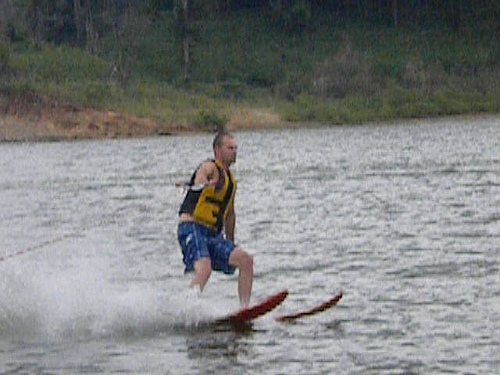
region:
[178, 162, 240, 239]
black and yellow life vest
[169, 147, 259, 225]
black and yellow life vest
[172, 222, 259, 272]
the shorts is blue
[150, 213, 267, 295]
the shorts is blue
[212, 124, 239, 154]
man has short hair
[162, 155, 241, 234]
yellow and black vest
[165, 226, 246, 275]
man has blue shorts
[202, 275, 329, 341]
red skis on water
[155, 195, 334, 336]
man is on skis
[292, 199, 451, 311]
water is light grey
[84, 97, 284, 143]
brown dirt on shore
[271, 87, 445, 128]
green plants on shore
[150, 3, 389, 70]
green trees in distance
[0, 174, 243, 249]
cable next to man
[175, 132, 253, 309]
the man on the water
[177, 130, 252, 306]
the man dressed for water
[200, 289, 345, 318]
the skis under the man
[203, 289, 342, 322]
the skis on the water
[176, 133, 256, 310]
the man on the skis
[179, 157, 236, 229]
the vest on the man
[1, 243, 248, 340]
the water splashing up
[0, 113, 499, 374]
the body of water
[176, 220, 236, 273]
the shorts on the man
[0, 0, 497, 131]
the grass on land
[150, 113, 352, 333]
A man water skiing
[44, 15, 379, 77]
many trees in the background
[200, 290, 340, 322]
the surfboards are red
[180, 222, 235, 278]
he is wearing a blue short pant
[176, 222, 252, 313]
the two legs of the surfer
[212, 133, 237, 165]
the head of the surfer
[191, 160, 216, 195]
one extended arm of the surfer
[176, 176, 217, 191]
his hand holding the cord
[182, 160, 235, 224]
this is a black and yellow jacket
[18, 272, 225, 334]
the foamy water made by the surfboards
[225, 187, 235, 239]
the other arm of the surfer